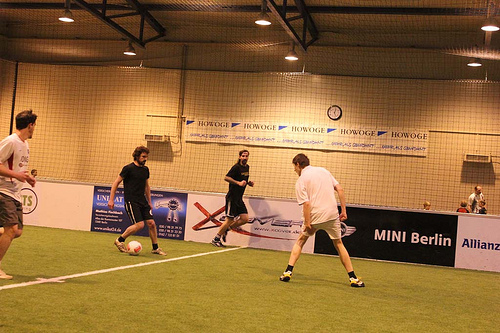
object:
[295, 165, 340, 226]
shirt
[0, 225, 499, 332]
court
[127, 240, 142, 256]
ball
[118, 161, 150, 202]
shirt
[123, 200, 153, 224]
shorts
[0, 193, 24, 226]
shorts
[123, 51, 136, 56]
light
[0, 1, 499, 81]
roof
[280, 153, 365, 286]
person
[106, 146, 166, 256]
person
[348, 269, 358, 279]
sock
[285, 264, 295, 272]
sock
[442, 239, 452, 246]
text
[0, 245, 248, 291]
line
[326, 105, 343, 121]
clock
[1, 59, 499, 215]
wall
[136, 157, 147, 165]
beard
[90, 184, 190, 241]
advertisement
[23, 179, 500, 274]
wall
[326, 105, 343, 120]
frame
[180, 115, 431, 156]
banner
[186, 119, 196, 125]
triangle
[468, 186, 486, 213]
adult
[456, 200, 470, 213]
child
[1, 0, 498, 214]
net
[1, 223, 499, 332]
turf